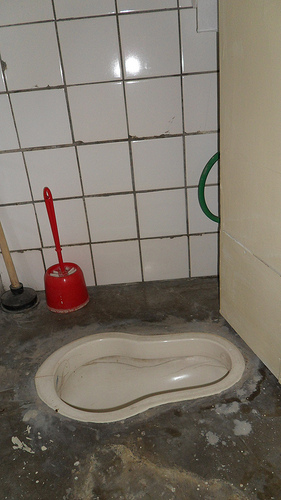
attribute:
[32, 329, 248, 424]
toilet — white, clean, ceramic, shiny, stained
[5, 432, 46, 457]
spots — white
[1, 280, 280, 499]
floor — old, grey, stained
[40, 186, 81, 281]
toilet brush — white, red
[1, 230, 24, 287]
handle — brown, wood, wooden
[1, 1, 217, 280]
tiles — white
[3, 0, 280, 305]
wall — white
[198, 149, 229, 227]
hose — green, plastic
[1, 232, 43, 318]
plunger — rubber, black